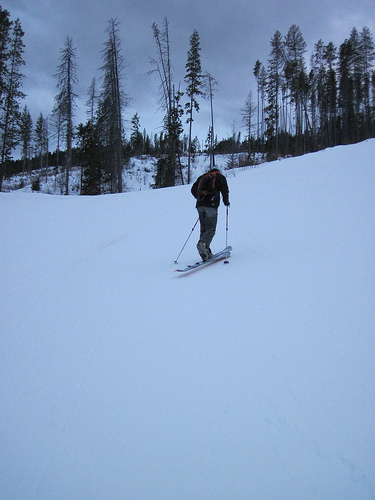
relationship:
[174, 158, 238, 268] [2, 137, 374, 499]
skier on slope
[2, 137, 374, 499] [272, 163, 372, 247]
slope covered in snow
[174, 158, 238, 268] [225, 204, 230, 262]
skier holding ski pole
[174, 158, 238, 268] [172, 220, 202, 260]
skier holding ski pole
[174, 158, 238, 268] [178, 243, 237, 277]
skier on skies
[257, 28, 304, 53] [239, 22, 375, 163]
top of trees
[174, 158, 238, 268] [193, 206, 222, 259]
skier wearing pants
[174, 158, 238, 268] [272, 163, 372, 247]
skier on snow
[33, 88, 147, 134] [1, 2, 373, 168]
cloud in sky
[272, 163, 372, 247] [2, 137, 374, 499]
snow on slope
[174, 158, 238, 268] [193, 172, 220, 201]
skier wearing backpack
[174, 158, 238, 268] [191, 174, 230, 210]
skier wearing jacket